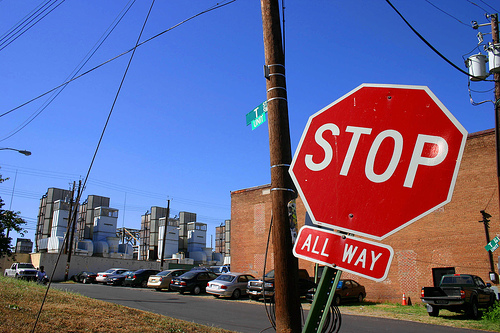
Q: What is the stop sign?
A: Red and white.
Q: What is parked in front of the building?
A: The cars.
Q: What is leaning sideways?
A: The stop sign.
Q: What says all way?
A: Red and white sign.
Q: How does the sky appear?
A: Clear and blue.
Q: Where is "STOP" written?
A: On red sign.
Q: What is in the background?
A: Buildings.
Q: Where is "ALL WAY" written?
A: On bottom red sign.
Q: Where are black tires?
A: On the cars.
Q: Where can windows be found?
A: On cars.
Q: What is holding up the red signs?
A: Green post.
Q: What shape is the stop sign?
A: Octagon.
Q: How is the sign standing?
A: It is leaning.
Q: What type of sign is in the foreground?
A: Stop Sign.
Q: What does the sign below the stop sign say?
A: All way.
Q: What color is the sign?
A: Red and white.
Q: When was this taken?
A: Daytime.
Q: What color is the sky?
A: Blue.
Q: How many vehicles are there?
A: Ten.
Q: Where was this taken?
A: On the street.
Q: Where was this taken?
A: A street corner.